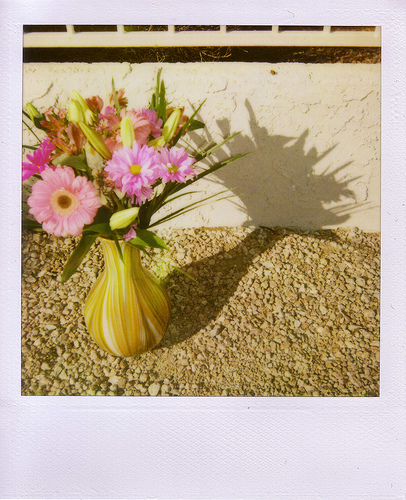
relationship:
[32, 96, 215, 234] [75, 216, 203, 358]
flowers in vase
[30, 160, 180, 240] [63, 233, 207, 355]
flowers in vase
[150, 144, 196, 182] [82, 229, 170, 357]
flower in a pot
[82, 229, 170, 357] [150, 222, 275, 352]
pot and its shadow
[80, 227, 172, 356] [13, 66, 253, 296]
vase holding flowers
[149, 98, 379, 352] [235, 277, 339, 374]
shadow on gravel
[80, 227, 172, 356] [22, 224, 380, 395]
vase sitting gravel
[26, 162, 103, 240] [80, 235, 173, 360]
flower in yellow vase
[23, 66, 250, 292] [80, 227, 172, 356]
boquet in vase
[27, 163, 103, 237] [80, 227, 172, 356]
flower in vase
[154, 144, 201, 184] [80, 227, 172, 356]
flower in vase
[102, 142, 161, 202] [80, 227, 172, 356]
flower in vase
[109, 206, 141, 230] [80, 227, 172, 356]
bud in vase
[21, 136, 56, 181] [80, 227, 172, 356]
flower in vase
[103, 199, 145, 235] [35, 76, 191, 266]
bud of a flower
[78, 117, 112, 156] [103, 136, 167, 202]
bud of a flower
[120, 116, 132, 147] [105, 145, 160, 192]
bud of a flower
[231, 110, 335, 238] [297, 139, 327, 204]
shadow on ground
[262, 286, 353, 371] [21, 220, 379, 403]
gravel on ground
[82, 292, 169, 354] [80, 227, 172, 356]
base of vase